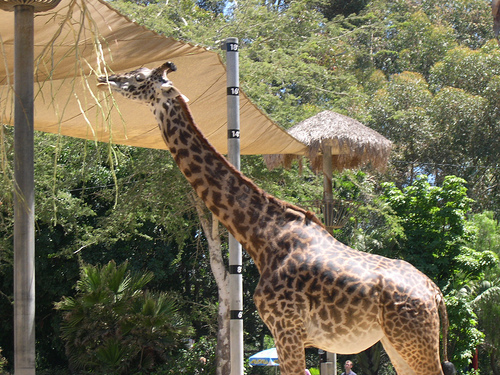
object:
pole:
[315, 142, 341, 374]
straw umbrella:
[268, 107, 394, 168]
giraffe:
[95, 58, 452, 370]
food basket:
[317, 193, 354, 232]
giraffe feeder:
[0, 3, 115, 136]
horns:
[155, 61, 174, 76]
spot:
[282, 254, 299, 276]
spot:
[190, 152, 204, 164]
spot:
[185, 124, 193, 134]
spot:
[350, 295, 360, 307]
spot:
[383, 290, 393, 300]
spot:
[308, 312, 318, 332]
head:
[339, 357, 354, 370]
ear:
[145, 61, 185, 82]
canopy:
[3, 7, 320, 181]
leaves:
[84, 53, 113, 115]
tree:
[33, 15, 125, 262]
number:
[228, 127, 242, 139]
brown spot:
[187, 139, 204, 163]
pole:
[10, 18, 42, 369]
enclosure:
[19, 18, 491, 365]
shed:
[0, 0, 312, 374]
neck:
[161, 90, 307, 259]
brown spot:
[269, 207, 309, 257]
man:
[340, 357, 362, 374]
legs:
[377, 290, 442, 374]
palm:
[77, 266, 182, 358]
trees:
[61, 252, 168, 359]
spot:
[331, 283, 350, 311]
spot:
[322, 298, 352, 328]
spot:
[397, 308, 408, 324]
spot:
[345, 313, 368, 333]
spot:
[265, 296, 288, 324]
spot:
[285, 259, 297, 276]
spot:
[223, 189, 238, 210]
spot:
[163, 116, 178, 136]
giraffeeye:
[133, 75, 145, 85]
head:
[93, 62, 170, 104]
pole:
[470, 341, 480, 373]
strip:
[222, 130, 243, 140]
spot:
[240, 188, 259, 222]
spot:
[215, 181, 227, 206]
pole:
[221, 54, 248, 371]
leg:
[269, 337, 322, 371]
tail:
[433, 299, 458, 372]